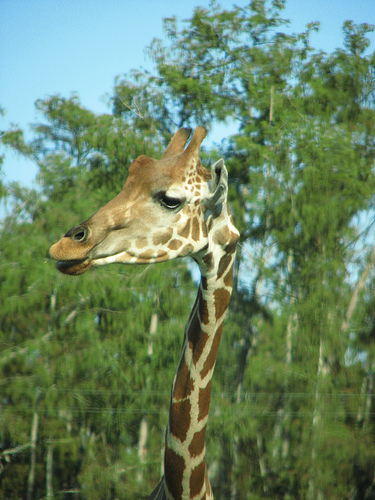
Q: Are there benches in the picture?
A: No, there are no benches.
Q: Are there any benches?
A: No, there are no benches.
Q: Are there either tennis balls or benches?
A: No, there are no benches or tennis balls.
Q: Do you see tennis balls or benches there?
A: No, there are no benches or tennis balls.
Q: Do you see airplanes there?
A: No, there are no airplanes.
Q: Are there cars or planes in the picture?
A: No, there are no planes or cars.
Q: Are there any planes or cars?
A: No, there are no planes or cars.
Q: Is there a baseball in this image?
A: No, there are no baseballs.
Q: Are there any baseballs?
A: No, there are no baseballs.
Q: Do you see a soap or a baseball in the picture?
A: No, there are no baseballs or soaps.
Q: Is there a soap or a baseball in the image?
A: No, there are no baseballs or soaps.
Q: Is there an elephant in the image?
A: No, there are no elephants.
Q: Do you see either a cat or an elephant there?
A: No, there are no elephants or cats.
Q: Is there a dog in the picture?
A: No, there are no dogs.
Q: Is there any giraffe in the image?
A: Yes, there is a giraffe.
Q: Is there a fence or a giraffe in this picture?
A: Yes, there is a giraffe.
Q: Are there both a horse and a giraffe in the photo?
A: No, there is a giraffe but no horses.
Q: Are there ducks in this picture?
A: No, there are no ducks.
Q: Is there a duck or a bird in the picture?
A: No, there are no ducks or birds.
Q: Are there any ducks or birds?
A: No, there are no ducks or birds.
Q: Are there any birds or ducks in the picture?
A: No, there are no ducks or birds.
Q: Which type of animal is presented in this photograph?
A: The animal is a giraffe.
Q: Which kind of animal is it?
A: The animal is a giraffe.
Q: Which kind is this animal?
A: This is a giraffe.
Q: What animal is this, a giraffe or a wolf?
A: This is a giraffe.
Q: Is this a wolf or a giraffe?
A: This is a giraffe.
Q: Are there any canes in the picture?
A: No, there are no canes.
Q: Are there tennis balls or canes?
A: No, there are no canes or tennis balls.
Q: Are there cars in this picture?
A: No, there are no cars.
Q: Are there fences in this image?
A: Yes, there is a fence.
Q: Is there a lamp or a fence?
A: Yes, there is a fence.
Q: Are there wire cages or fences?
A: Yes, there is a wire fence.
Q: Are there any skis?
A: No, there are no skis.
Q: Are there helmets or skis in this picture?
A: No, there are no skis or helmets.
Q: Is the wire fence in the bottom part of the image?
A: Yes, the fence is in the bottom of the image.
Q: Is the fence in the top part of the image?
A: No, the fence is in the bottom of the image.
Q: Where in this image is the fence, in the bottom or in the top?
A: The fence is in the bottom of the image.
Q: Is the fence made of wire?
A: Yes, the fence is made of wire.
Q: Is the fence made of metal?
A: No, the fence is made of wire.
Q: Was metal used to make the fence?
A: No, the fence is made of wire.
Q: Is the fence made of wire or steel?
A: The fence is made of wire.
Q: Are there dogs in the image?
A: No, there are no dogs.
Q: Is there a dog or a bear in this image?
A: No, there are no dogs or bears.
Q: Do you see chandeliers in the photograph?
A: No, there are no chandeliers.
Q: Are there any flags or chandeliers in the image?
A: No, there are no chandeliers or flags.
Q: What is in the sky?
A: The clouds are in the sky.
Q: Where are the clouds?
A: The clouds are in the sky.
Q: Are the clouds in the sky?
A: Yes, the clouds are in the sky.